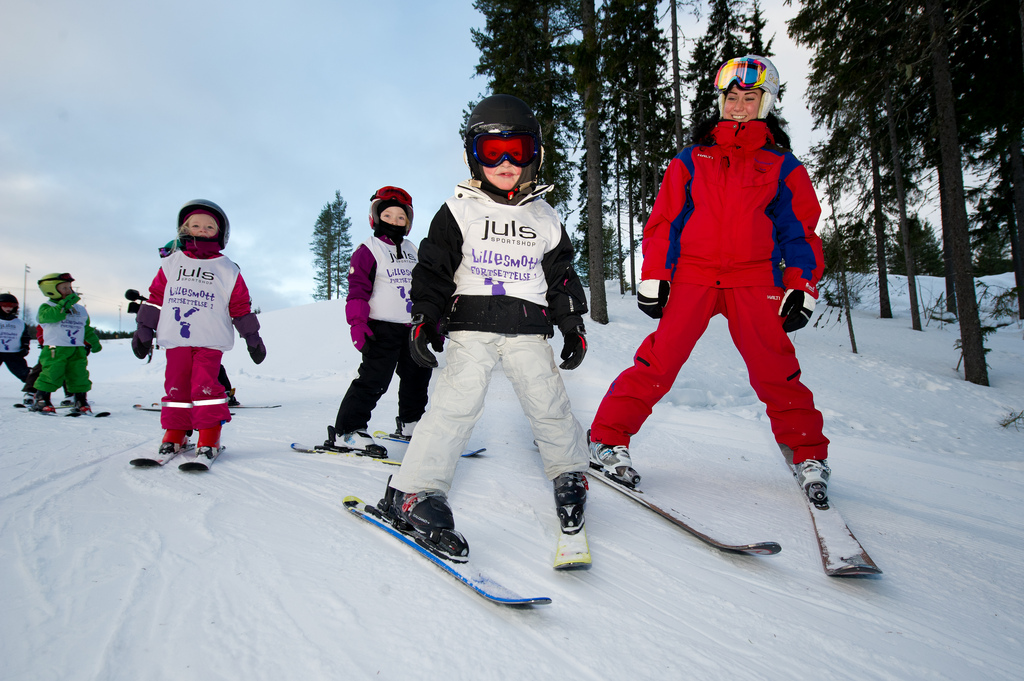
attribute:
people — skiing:
[0, 50, 885, 609]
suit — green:
[32, 296, 103, 396]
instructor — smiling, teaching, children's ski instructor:
[588, 53, 843, 507]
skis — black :
[132, 444, 225, 476]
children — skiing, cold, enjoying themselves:
[0, 90, 600, 560]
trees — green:
[310, 0, 1023, 387]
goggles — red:
[474, 132, 538, 164]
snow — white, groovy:
[0, 263, 1021, 679]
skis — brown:
[585, 465, 887, 582]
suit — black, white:
[390, 176, 596, 494]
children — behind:
[2, 182, 430, 463]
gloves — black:
[406, 317, 590, 373]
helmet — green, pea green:
[36, 271, 75, 297]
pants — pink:
[160, 343, 235, 431]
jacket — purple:
[342, 247, 377, 303]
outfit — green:
[34, 300, 104, 401]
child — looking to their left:
[29, 270, 101, 414]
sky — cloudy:
[2, 2, 496, 338]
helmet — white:
[711, 54, 781, 117]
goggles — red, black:
[373, 183, 412, 205]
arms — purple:
[346, 243, 380, 349]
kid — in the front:
[327, 77, 645, 639]